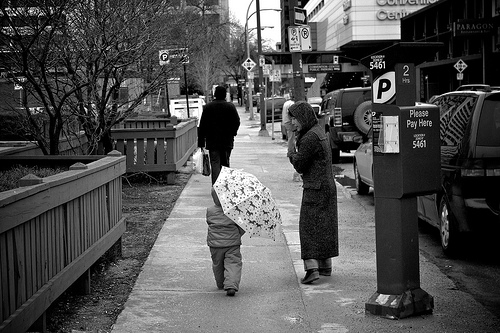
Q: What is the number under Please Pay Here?
A: 5461.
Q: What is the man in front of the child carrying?
A: A briefcase.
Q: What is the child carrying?
A: An umbrella.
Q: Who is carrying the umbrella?
A: A child.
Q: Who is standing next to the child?
A: A woman.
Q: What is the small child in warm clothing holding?
A: An umbrella.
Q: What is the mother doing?
A: Walking and talking to a child.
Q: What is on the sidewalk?
A: A two hour sidewalk parking meter.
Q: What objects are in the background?
A: Numerous directional pole signs.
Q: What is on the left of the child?
A: Park trees wooden enclosures.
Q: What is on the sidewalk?
A: Dusting snow.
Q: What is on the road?
A: Vehicles.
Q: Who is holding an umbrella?
A: A Small child.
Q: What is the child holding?
A: An open umbrella.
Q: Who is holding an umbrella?
A: Little boy.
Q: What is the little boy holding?
A: An umbrella.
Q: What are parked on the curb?
A: Cars.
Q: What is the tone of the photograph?
A: Black and white.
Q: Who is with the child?
A: A woman.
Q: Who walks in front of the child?
A: A man.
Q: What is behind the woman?
A: A parking meter.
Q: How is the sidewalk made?
A: Of concrete.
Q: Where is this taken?
A: A city street.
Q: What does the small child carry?
A: An umbrella.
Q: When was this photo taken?
A: Daytime.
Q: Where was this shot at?
A: Sidewalk.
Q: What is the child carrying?
A: Umbrella.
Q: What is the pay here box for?
A: Parking.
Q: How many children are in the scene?
A: 1.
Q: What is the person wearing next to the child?
A: Dress.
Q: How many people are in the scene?
A: 3.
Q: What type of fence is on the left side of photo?
A: Wooden.